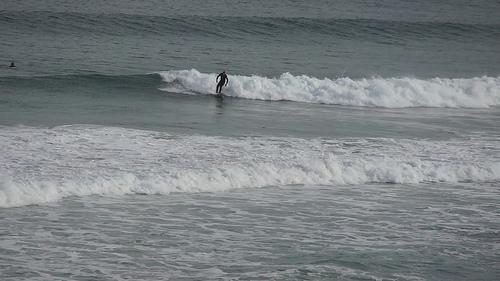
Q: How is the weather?
A: Fair.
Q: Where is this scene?
A: Ocean.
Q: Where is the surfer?
A: Water.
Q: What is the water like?
A: Choppy.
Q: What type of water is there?
A: Saltwater.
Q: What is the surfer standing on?
A: Surfboard.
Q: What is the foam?
A: Bubbly water.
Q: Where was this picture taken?
A: Ocean.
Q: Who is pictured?
A: A man.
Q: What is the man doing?
A: Surfing.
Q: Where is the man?
A: On the surfboard.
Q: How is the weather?
A: Overcast.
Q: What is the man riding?
A: Waves.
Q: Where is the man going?
A: Shore.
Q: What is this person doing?
A: Surfing.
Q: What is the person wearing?
A: Wetsuit.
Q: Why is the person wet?
A: In the water.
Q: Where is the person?
A: In the ocean.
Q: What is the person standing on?
A: Surfboard.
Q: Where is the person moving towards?
A: The shore.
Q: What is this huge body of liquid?
A: Water.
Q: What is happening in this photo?
A: A man is surfing.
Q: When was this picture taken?
A: Daytime.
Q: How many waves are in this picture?
A: Two.